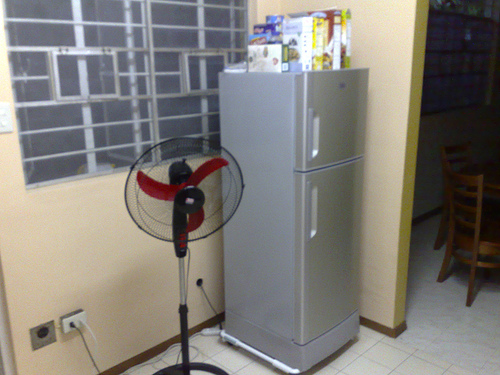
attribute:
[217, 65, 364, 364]
fridge — silver, silvery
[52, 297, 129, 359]
cable — white and black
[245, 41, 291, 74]
packet — multicolored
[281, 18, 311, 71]
packet — multicolored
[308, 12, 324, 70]
packet — multicolored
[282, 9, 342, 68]
packet — multicolored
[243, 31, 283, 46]
packet — multicolored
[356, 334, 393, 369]
kitchen floor — white, tiled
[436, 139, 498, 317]
chairs — wooden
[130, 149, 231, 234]
fan — red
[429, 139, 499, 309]
chairs — wooden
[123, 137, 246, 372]
fan — standing, black and red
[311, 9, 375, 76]
packet — multicolored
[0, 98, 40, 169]
switch — white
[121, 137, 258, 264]
air fan — black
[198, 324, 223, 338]
surge protector — white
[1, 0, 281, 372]
wall — clean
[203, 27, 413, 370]
fridge — grey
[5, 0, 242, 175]
windows — white, bar framed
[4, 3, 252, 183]
windows — white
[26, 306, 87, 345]
outlets — electric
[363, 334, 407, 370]
tile — white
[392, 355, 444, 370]
tile — white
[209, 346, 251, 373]
tile — white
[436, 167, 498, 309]
chair — brown, wooden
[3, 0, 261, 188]
window — grilled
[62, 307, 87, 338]
socket — white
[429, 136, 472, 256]
chair — wooden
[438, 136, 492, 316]
seats — brown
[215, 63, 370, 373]
refrigerator — stainless, colored